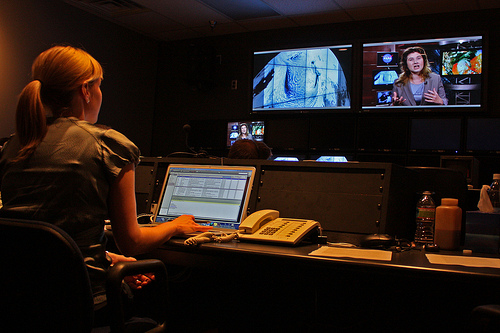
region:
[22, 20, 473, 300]
A person is inside an office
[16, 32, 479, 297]
The person is inside a building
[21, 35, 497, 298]
The person is watching some television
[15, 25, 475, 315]
The person is using a laptop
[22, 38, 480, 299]
The person is sitting in a chair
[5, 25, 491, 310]
The person is working very late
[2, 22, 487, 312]
The person is watching a TV screen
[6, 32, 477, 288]
The person is out in the evening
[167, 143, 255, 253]
computer monitor on desk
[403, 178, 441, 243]
bottle of water without cap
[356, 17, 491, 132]
large tv on wall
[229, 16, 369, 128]
large tv on left side of wall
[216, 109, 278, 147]
small tv monitor below upper tv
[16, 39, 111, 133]
blonde woman with pony tail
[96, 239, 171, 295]
black arm on rolling chair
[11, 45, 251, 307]
a woman using a laptop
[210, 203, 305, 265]
a small white landline phone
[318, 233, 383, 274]
a small white piece of paper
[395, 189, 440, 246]
a small clear empty water bottle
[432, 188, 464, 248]
a small bottle of some liquid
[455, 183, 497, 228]
tissue sticking out of a box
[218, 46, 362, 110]
a small black tv screen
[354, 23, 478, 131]
a woman talking on a tv screen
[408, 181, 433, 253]
plastic water bottle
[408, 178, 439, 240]
plastic water bottle with the cap missing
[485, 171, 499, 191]
plastic water bottle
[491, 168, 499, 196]
white cap on plastic water bottle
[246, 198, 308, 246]
white telephone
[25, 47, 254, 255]
woman is on her computer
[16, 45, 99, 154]
woman's hair is blonde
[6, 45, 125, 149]
woman's hair is tied back in a ponytail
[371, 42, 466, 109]
woman on t.v. screen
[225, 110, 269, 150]
woman on t.v. screen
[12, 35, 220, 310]
A woman sitting behind a laptop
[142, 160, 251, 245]
A laptop turned on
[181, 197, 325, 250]
A landline telephone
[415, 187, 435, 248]
A clear bottle of water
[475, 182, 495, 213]
A white tissue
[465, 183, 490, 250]
A box of tissues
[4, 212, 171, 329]
A desk chair with black handles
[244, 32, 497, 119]
Two television monitors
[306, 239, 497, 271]
Papers on the desk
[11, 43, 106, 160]
A woman with a blonde ponytail